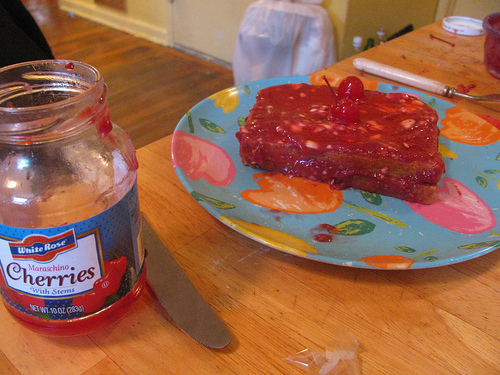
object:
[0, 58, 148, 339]
jar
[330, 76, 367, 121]
cherries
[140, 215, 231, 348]
blade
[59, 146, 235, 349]
knife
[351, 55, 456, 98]
handle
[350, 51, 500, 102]
fork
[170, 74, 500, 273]
plate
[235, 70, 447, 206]
food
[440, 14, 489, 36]
lid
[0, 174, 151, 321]
label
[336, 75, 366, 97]
cherry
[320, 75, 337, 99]
stem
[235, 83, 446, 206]
bread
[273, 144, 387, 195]
jam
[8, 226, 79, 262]
logo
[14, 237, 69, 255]
white rose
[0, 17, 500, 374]
table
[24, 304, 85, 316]
weight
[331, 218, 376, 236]
leaf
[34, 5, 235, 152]
floor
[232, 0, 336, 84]
plastic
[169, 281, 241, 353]
top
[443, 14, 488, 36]
cover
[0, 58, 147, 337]
glass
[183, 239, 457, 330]
top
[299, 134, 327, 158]
flecks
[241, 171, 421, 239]
pattern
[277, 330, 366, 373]
cellophane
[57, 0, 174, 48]
baseboard